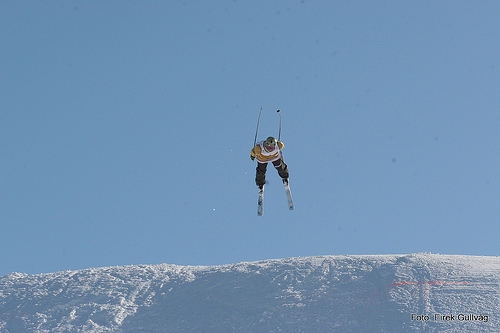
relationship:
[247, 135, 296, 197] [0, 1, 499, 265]
man in sky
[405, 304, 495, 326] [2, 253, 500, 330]
logo near ground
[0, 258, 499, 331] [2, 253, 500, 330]
snow on ground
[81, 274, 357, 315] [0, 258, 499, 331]
tracks in snow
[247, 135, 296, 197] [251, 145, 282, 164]
man wearing jacket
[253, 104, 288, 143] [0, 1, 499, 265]
poles in sky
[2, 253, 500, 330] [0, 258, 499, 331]
ground covered in snow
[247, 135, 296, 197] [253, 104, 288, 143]
man holding poles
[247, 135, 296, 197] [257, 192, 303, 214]
man wearing skis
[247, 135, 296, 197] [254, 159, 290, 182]
man wearing pants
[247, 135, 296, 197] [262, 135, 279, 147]
man wearing helmet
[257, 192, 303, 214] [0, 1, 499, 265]
skis in sky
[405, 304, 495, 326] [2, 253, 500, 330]
logo on ground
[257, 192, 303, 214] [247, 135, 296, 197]
skis on man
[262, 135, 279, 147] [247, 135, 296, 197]
helmet on man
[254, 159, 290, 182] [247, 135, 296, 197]
pants on man